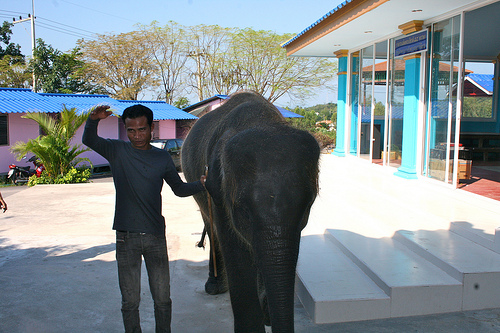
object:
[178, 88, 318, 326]
elephant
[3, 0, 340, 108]
distance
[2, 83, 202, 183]
building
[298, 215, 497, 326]
stairs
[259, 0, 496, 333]
building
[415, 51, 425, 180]
trim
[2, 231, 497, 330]
shadow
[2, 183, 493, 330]
pavement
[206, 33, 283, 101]
trees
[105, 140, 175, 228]
shirt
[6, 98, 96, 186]
plant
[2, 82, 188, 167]
house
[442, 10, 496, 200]
windows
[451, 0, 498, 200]
door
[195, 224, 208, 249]
tail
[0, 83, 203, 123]
roof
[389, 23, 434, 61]
sign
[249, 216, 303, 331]
trunk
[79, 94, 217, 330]
man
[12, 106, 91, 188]
bush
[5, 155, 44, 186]
moped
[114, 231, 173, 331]
jeans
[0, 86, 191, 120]
awning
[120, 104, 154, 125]
hair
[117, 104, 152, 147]
head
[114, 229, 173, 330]
blue jeans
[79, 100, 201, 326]
person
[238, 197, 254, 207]
eye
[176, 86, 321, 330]
animal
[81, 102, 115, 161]
arm/hand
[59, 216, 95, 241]
light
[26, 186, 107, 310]
ground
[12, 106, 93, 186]
tree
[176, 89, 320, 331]
an elephant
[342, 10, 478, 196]
front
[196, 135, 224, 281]
strap